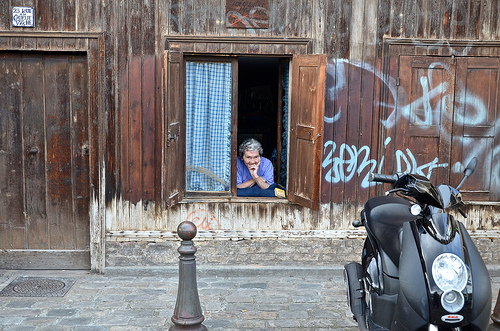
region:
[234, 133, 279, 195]
man in blue shirt leaning out window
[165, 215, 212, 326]
decorative metal parking post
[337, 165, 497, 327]
shiny black motorcycle front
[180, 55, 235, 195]
long blue and white checkered curtain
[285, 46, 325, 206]
open wooden window shutter with latch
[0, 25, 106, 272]
tall wooden door is closed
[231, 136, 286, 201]
a woman by the window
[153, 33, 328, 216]
a window of the building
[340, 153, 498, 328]
a scooter in the sidewalk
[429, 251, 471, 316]
lights on the scooter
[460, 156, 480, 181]
a side mirror of the scooter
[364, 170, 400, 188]
a handle grip of the scooter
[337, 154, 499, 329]
a black scooter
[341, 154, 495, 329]
a black scooter in the sidewalk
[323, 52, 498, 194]
graffiti on the wall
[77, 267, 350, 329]
brick sidwalk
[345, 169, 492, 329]
Black moped parked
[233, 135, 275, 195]
Old woman wearing blue shirt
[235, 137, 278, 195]
Old woman in a window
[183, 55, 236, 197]
Blue and white curtain in a window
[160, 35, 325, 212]
Wood shutters on a window with a curtain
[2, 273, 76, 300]
Manhole cover on a paved street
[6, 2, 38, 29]
White sign on a wood wall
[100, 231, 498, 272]
Stone foundation on a building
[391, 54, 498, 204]
Closed wooden shutters with graffiti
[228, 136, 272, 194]
woman leaning forward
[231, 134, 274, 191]
woman with grey hair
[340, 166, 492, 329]
black motorcycle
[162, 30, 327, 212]
brown wood window open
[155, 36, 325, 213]
woman leaning on an open window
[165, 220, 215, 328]
shiny gray post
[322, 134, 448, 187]
blue graffiti on a wall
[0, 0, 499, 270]
dark wood building with graffiti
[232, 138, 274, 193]
woman wearing purple shirt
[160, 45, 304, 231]
A window on a building.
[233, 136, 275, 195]
woman in blue shirt looking through a window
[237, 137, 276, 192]
woman with gray hair looking through a window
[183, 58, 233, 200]
blue and white checkered curtain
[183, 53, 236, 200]
blue and white curtain hanging in a window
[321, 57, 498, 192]
light blue writing on the side of a building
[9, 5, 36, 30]
small white sign with black letters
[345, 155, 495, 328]
dark gray motorcycle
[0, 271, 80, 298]
gray manhole cover on a stone sidewalk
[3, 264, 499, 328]
light and dark gray stone sidewalk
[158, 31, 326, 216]
brown wooden doors for the window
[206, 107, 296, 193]
person in the window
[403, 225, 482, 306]
light on the vehicle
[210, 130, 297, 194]
person wearing a blue shirt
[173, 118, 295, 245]
person looking towards camera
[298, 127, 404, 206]
writing on the building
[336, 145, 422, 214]
handlebar on the bike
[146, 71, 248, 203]
curtain on the window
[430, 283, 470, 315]
Light of a vehicle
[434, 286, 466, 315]
Light of a black vehicle